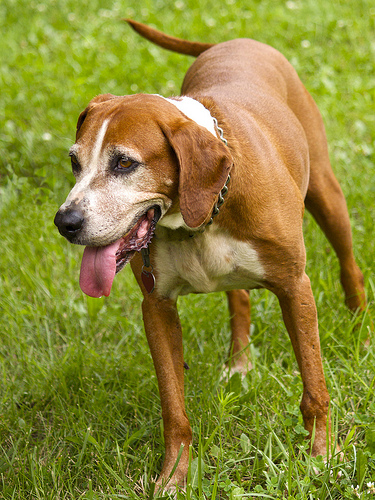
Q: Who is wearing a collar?
A: The dog.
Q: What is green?
A: Grass.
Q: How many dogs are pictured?
A: One.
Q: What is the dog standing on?
A: It is on grass.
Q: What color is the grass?
A: The grass is green.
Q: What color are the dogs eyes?
A: They are brown.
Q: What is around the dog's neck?
A: He's wearing a collar.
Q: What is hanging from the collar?
A: A heart is hanging down.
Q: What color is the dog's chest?
A: Its chest is white.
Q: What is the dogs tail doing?
A: Wagging.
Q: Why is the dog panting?
A: It is hot.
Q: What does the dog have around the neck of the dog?
A: Collar.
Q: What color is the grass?
A: Green.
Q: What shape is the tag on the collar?
A: Heart.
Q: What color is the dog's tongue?
A: Pink.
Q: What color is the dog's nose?
A: Black.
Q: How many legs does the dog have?
A: 4.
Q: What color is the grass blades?
A: Green.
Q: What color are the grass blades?
A: Green.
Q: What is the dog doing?
A: Playing around.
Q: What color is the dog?
A: Brown and white.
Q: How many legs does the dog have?
A: 4.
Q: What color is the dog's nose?
A: Black.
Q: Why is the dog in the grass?
A: He wants to have outside time.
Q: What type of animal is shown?
A: Dog.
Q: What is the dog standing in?
A: Grass.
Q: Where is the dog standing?
A: On grass.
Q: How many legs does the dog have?
A: Four.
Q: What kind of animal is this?
A: Dog.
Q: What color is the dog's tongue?
A: Pink.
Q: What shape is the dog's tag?
A: Heart.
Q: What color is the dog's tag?
A: Red.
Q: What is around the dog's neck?
A: A collar.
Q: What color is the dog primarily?
A: Brown.